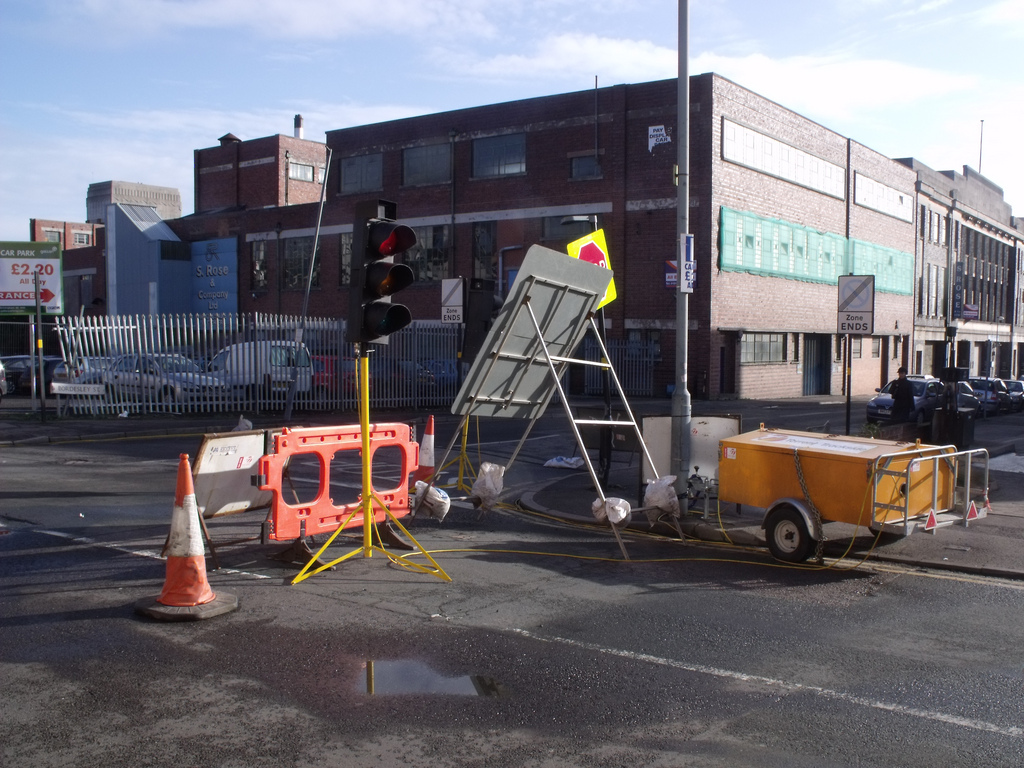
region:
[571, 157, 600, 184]
window on the building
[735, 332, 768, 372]
window on the building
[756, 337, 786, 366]
window on the building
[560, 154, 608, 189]
window on the building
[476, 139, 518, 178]
window on the building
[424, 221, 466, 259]
window on the building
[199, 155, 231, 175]
window on a building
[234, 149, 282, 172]
window on a building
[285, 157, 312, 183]
window on a building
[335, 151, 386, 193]
window on a building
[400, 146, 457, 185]
window on a building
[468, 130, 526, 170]
window on a building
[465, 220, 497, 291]
window on a building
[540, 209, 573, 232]
window on a building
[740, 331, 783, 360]
window on a building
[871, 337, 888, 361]
window on a building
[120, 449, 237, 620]
orange traffic cone with white stripe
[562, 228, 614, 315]
yellowsign with red on it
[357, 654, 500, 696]
small mud puddle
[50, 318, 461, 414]
tall fence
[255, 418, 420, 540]
plastic orange barrier section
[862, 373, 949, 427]
car parked on the curb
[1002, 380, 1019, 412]
car parked on the curb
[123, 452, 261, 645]
orange and white cone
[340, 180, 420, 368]
a black traffic signal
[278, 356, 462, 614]
yellow pole on ground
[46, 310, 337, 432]
tall fence in background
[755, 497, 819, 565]
small wheel on cart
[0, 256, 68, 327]
white and red sign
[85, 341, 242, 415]
car parked behind fence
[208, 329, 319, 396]
white van behind fence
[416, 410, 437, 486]
orange and white cone